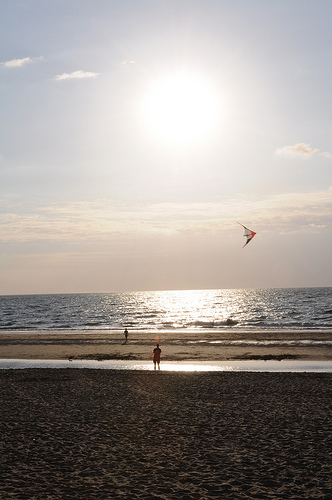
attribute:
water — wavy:
[4, 293, 326, 328]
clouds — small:
[51, 65, 103, 86]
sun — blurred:
[125, 44, 266, 169]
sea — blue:
[1, 286, 331, 332]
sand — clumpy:
[0, 368, 327, 493]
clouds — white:
[51, 68, 101, 80]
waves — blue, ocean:
[0, 286, 331, 328]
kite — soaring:
[232, 206, 288, 276]